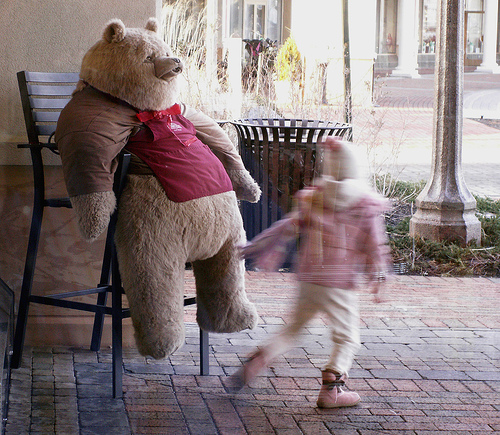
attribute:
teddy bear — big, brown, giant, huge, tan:
[57, 17, 261, 357]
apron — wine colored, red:
[125, 109, 235, 202]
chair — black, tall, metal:
[7, 69, 216, 399]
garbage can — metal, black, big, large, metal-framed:
[228, 118, 352, 269]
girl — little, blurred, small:
[230, 135, 388, 408]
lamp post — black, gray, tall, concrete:
[409, 2, 484, 246]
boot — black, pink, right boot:
[317, 368, 362, 407]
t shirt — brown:
[55, 84, 248, 194]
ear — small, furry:
[102, 18, 125, 44]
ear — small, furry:
[146, 17, 158, 32]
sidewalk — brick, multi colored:
[0, 268, 498, 434]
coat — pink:
[258, 178, 388, 291]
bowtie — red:
[137, 104, 182, 122]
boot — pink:
[231, 352, 264, 389]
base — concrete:
[408, 217, 481, 246]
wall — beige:
[1, 1, 170, 351]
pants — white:
[260, 283, 363, 379]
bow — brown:
[323, 378, 345, 389]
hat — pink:
[324, 133, 363, 180]